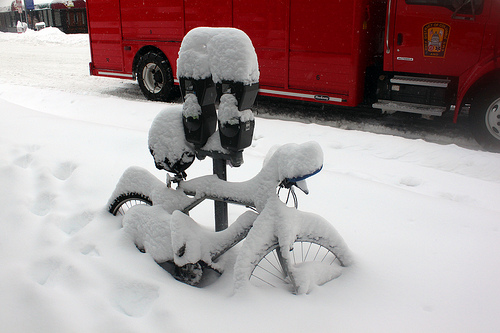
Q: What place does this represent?
A: It represents the road.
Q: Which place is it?
A: It is a road.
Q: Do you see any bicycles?
A: Yes, there is a bicycle.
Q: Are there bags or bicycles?
A: Yes, there is a bicycle.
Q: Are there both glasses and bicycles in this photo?
A: No, there is a bicycle but no glasses.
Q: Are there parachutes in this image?
A: No, there are no parachutes.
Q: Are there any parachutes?
A: No, there are no parachutes.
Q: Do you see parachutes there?
A: No, there are no parachutes.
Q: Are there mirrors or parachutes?
A: No, there are no parachutes or mirrors.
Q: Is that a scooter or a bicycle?
A: That is a bicycle.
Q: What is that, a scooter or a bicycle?
A: That is a bicycle.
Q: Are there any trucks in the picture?
A: Yes, there is a truck.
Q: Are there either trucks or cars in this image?
A: Yes, there is a truck.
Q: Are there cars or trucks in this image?
A: Yes, there is a truck.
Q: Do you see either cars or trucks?
A: Yes, there is a truck.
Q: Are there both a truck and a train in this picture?
A: No, there is a truck but no trains.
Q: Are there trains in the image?
A: No, there are no trains.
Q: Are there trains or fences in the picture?
A: No, there are no trains or fences.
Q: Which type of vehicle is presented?
A: The vehicle is a truck.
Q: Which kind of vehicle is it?
A: The vehicle is a truck.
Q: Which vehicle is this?
A: That is a truck.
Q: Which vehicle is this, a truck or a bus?
A: That is a truck.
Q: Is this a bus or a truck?
A: This is a truck.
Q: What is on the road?
A: The truck is on the road.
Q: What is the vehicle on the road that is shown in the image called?
A: The vehicle is a truck.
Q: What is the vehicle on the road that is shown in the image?
A: The vehicle is a truck.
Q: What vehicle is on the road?
A: The vehicle is a truck.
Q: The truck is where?
A: The truck is on the road.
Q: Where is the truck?
A: The truck is on the road.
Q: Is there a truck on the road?
A: Yes, there is a truck on the road.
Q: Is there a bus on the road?
A: No, there is a truck on the road.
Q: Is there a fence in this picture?
A: No, there are no fences.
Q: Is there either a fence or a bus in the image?
A: No, there are no fences or buses.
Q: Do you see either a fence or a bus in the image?
A: No, there are no fences or buses.